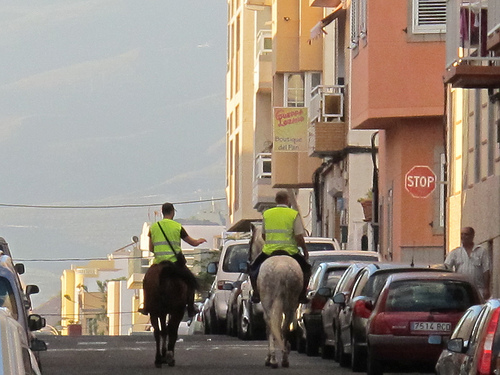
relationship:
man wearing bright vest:
[138, 202, 208, 318] [149, 217, 185, 260]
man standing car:
[432, 226, 493, 303] [341, 257, 453, 365]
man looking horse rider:
[138, 202, 208, 318] [248, 184, 314, 265]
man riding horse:
[138, 202, 208, 318] [143, 261, 187, 366]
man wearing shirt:
[432, 226, 493, 303] [437, 240, 496, 300]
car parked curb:
[359, 252, 477, 353] [409, 354, 437, 367]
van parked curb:
[175, 204, 291, 354] [395, 357, 417, 372]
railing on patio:
[443, 4, 498, 64] [438, 3, 498, 88]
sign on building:
[404, 165, 436, 198] [348, 0, 444, 265]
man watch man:
[432, 226, 493, 303] [138, 202, 208, 318]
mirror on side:
[442, 338, 466, 353] [1, 253, 44, 373]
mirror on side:
[352, 296, 371, 319] [1, 253, 44, 373]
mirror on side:
[330, 292, 346, 306] [1, 253, 44, 373]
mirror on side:
[219, 284, 233, 291] [1, 253, 44, 373]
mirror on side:
[205, 261, 217, 278] [1, 253, 44, 373]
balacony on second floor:
[299, 81, 346, 126] [299, 65, 366, 165]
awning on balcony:
[301, 18, 345, 51] [297, 73, 349, 158]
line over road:
[0, 190, 225, 219] [41, 328, 345, 374]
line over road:
[13, 243, 200, 264] [41, 328, 345, 374]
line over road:
[34, 306, 141, 318] [41, 328, 345, 374]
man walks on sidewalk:
[437, 231, 497, 293] [432, 283, 487, 361]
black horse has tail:
[142, 261, 190, 369] [159, 256, 204, 290]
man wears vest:
[136, 201, 200, 314] [147, 219, 184, 264]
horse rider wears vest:
[248, 190, 312, 304] [260, 206, 300, 258]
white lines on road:
[52, 341, 272, 355] [41, 328, 345, 374]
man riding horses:
[138, 202, 208, 318] [116, 197, 387, 374]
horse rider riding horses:
[248, 190, 312, 304] [116, 197, 387, 374]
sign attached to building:
[400, 166, 440, 197] [441, 79, 484, 257]